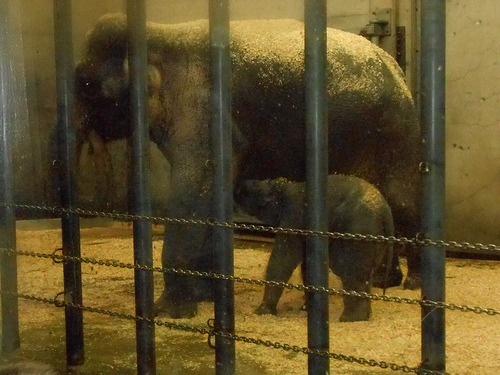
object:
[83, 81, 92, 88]
eye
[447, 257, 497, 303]
straw floor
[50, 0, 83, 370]
bar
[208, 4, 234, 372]
bar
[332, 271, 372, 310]
leg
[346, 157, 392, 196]
ground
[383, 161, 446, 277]
leg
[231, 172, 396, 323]
baby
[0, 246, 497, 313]
chain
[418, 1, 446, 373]
bar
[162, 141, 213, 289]
leg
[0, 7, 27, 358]
metal post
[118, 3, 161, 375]
post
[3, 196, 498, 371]
fencing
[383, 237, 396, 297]
gray tail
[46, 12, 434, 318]
adult elephant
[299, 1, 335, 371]
bar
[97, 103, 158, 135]
floor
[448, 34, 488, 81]
crack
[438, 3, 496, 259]
wall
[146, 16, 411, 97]
dirt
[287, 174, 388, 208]
dirt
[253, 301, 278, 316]
foot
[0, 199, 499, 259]
chain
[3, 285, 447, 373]
chain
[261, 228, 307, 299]
leg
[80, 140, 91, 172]
tusk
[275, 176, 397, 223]
back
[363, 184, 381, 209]
hay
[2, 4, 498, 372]
pen